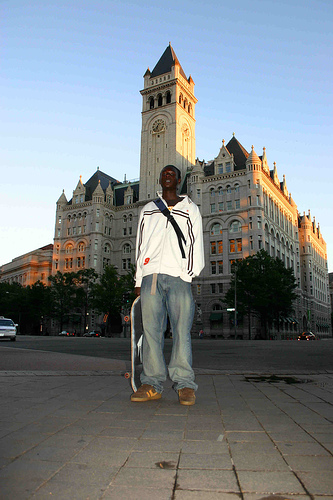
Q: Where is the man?
A: In front of an abbey.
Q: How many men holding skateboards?
A: One.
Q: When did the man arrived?
A: Earlier.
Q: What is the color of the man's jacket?
A: White.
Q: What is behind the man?
A: An abbey.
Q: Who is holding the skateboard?
A: A man.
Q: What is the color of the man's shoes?
A: Brown.